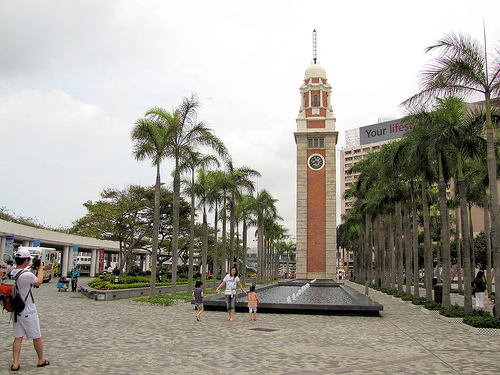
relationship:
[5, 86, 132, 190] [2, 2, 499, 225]
cloud in sky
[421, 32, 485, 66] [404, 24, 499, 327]
leaves of tree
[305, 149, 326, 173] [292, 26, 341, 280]
clock on tower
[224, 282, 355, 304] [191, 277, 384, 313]
water in pool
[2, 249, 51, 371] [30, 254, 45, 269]
man with camera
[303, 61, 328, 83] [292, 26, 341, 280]
dome on tower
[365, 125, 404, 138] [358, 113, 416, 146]
words on sign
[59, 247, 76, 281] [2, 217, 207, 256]
columns under structure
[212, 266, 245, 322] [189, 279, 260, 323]
woman with children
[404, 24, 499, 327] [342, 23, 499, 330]
tree in row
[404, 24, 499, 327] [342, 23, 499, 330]
tree in a row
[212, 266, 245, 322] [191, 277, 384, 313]
mother by fountain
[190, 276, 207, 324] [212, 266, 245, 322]
child by mother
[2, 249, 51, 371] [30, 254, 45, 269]
man taking pictures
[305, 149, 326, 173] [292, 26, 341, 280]
clock on building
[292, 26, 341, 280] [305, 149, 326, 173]
building with clock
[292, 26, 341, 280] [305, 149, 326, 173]
tower with clock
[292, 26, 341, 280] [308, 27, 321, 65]
building with point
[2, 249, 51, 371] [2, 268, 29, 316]
man with backpack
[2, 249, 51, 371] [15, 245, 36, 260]
man with hat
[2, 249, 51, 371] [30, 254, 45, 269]
man taking photograph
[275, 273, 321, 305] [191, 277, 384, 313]
fountain in pool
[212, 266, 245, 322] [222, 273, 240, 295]
woman wearing shirt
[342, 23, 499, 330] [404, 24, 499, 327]
row of palm trees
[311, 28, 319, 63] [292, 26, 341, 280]
antennae on tower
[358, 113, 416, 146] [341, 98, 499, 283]
sign on building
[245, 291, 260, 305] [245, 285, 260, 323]
shirt on girl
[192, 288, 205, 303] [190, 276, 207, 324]
shirt on girl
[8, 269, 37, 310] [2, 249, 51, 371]
shirt on man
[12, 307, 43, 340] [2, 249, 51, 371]
shorts are on man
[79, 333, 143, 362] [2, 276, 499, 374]
pattern on ground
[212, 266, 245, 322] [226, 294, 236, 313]
woman wearing capris